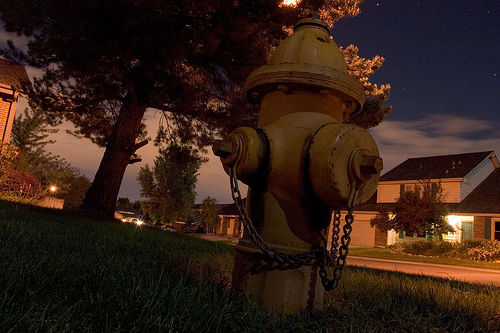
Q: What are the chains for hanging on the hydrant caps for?
A: So they don't get lost.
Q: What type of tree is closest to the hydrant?
A: Pine tree.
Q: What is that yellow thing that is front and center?
A: Fire hydrant.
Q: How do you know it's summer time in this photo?
A: Stars are close and bright.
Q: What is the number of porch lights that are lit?
A: 3.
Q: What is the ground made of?
A: Grass.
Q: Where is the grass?
A: On the ground.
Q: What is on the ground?
A: A fire hydrant.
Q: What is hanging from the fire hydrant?
A: Chains.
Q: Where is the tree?
A: On the grass.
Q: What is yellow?
A: Fire hydrant.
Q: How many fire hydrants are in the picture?
A: One.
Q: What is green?
A: Grass.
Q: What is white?
A: A house.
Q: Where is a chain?
A: On a fire hydrant.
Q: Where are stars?
A: In the sky.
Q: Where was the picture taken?
A: In a neighborhood.